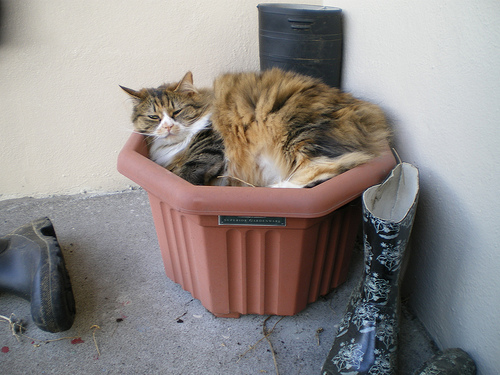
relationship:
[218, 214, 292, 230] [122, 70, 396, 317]
imprint on a holder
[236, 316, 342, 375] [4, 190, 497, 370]
twigs are on ground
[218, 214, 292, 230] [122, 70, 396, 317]
imprint on tub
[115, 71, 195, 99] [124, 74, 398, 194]
ears are on cat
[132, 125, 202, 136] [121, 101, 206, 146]
whiskers are on face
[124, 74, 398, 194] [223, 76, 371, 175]
cat has fur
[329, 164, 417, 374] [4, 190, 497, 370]
boot on ground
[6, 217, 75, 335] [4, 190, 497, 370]
boot on ground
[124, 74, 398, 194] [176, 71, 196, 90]
cat has an ear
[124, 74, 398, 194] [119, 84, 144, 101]
cat has an ear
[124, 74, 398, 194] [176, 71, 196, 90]
cat has a right ear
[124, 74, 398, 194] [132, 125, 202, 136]
cat has whiskers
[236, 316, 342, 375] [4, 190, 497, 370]
sticks are on ground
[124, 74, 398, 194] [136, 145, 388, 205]
cat laying down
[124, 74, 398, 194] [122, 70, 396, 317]
cat in a pot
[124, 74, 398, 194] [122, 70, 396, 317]
cat in a flower pot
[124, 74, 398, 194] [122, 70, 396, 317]
feline inside of a pot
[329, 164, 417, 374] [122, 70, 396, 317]
boot next to a flower pot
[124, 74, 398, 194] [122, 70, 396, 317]
cat inside a flower pot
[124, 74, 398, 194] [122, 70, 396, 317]
cat in a basket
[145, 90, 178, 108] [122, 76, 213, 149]
stripes are on top of head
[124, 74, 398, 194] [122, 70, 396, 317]
cat inside of a flower pot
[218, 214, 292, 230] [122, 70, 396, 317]
imprint on pot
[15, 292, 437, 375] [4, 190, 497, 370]
dirt on cement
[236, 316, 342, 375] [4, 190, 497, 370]
twigs are on cement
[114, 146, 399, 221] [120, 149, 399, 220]
pot has a lip